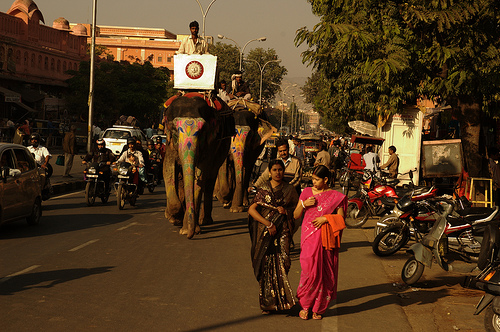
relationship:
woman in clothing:
[296, 162, 346, 323] [296, 186, 347, 312]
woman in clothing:
[247, 159, 303, 317] [250, 179, 301, 310]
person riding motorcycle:
[112, 138, 146, 183] [113, 161, 143, 211]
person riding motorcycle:
[81, 137, 117, 186] [79, 154, 114, 208]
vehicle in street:
[0, 141, 53, 234] [1, 164, 499, 330]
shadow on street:
[1, 263, 116, 298] [1, 164, 499, 330]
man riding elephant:
[175, 19, 214, 58] [162, 90, 237, 241]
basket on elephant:
[171, 50, 219, 94] [162, 90, 237, 241]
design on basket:
[185, 59, 205, 81] [171, 50, 219, 94]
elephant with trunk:
[162, 90, 237, 241] [171, 117, 206, 238]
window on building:
[165, 54, 174, 66] [65, 20, 189, 96]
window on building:
[156, 53, 164, 66] [65, 20, 189, 96]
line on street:
[1, 205, 168, 285] [1, 164, 499, 330]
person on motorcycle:
[81, 137, 117, 186] [79, 154, 114, 208]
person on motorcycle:
[112, 138, 146, 183] [113, 161, 143, 211]